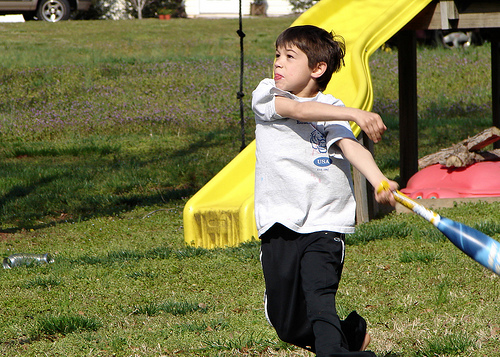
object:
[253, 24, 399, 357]
boy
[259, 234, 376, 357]
pants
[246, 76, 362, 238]
shirt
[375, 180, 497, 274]
bat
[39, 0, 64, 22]
wheel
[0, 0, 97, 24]
car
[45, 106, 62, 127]
flowers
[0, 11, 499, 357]
landscape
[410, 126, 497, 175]
logs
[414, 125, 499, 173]
wood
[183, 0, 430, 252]
slide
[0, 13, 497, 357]
ground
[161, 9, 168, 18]
plants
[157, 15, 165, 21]
pots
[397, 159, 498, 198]
dome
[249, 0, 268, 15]
box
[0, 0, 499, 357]
background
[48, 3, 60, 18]
hubcap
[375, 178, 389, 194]
tip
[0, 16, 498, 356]
grass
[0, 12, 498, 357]
park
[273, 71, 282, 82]
tongue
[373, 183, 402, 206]
hand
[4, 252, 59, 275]
slinky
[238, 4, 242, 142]
swing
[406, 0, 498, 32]
sandbox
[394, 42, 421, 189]
post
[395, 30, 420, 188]
jungle gym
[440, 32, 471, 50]
mask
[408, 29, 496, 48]
shadows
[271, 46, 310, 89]
face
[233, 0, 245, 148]
rope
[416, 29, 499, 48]
bottom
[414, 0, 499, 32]
deck